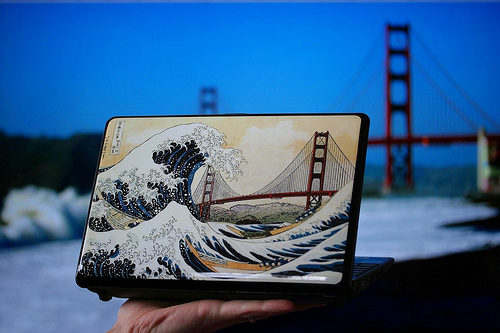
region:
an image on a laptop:
[70, 94, 362, 306]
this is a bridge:
[115, 15, 499, 225]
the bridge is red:
[218, 14, 492, 199]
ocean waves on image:
[90, 122, 257, 283]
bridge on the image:
[176, 120, 350, 225]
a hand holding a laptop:
[50, 66, 410, 331]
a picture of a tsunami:
[74, 107, 369, 292]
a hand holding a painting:
[70, 111, 374, 329]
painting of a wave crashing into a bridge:
[75, 107, 369, 289]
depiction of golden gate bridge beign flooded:
[70, 104, 374, 294]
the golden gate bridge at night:
[374, 20, 495, 192]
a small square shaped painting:
[72, 110, 367, 297]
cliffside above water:
[7, 124, 75, 262]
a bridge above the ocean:
[370, 18, 491, 203]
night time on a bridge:
[307, 8, 477, 106]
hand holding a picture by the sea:
[42, 94, 373, 325]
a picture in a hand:
[66, 53, 471, 332]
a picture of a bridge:
[110, 77, 492, 331]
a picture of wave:
[111, 104, 317, 288]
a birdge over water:
[347, 29, 493, 194]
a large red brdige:
[339, 33, 493, 168]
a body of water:
[34, 198, 139, 332]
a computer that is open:
[48, 91, 396, 321]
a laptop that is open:
[89, 105, 400, 323]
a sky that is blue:
[91, 2, 498, 179]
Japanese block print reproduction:
[71, 105, 374, 304]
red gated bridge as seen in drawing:
[45, 14, 482, 203]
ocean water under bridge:
[6, 166, 498, 323]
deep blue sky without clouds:
[9, 8, 498, 159]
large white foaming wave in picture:
[88, 127, 263, 271]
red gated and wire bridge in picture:
[191, 123, 351, 223]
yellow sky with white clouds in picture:
[101, 116, 355, 192]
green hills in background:
[1, 126, 97, 196]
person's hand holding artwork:
[75, 104, 375, 329]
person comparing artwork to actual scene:
[3, 0, 498, 323]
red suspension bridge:
[173, 24, 497, 194]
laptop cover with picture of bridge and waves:
[73, 109, 370, 285]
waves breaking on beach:
[3, 185, 499, 330]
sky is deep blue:
[0, 3, 497, 166]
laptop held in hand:
[71, 113, 396, 303]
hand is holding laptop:
[105, 288, 343, 331]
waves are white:
[2, 196, 499, 331]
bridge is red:
[196, 19, 497, 193]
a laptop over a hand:
[60, 96, 411, 325]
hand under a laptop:
[88, 286, 340, 332]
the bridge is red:
[350, 9, 499, 206]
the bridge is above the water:
[375, 16, 489, 227]